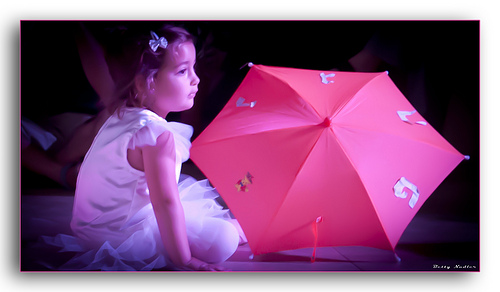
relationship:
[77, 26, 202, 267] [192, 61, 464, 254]
girl with umbrella